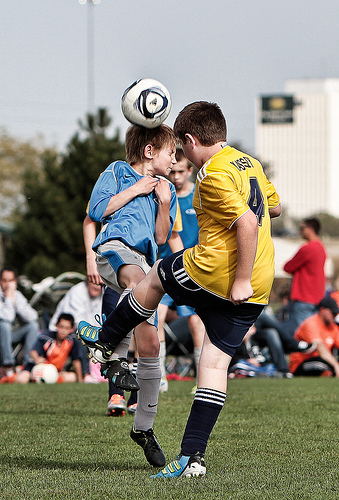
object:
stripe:
[195, 392, 225, 402]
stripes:
[130, 292, 156, 313]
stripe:
[193, 396, 224, 407]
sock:
[98, 290, 157, 349]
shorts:
[158, 247, 267, 362]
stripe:
[127, 295, 150, 318]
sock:
[182, 387, 225, 454]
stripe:
[172, 268, 185, 276]